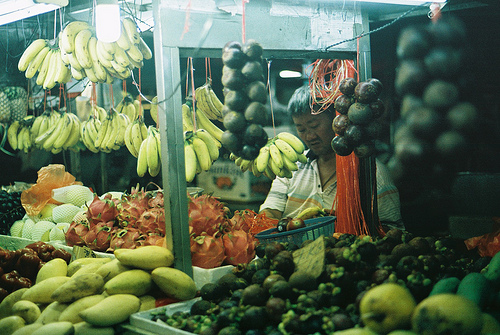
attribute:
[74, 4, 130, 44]
light bulb — hanging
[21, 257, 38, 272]
pepper — red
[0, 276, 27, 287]
pepper — red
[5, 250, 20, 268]
pepper — red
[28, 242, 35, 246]
pepper — red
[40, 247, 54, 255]
pepper — red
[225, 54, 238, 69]
fruit — hanging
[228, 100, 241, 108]
fruit — hanging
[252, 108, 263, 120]
fruit — hanging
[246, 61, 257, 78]
fruit — hanging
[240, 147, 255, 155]
fruit — hanging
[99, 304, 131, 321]
vegetable — yellow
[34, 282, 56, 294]
vegetable — yellow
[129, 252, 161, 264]
vegetable — yellow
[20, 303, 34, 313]
vegetable — yellow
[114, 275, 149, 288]
vegetable — yellow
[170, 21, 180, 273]
pole — gray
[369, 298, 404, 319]
mango — green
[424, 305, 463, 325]
mango — green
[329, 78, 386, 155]
avacado — green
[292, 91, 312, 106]
hair — gray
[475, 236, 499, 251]
bag — orange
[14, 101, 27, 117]
pinapple — green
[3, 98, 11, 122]
pineapple — green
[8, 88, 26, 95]
pineapple — green